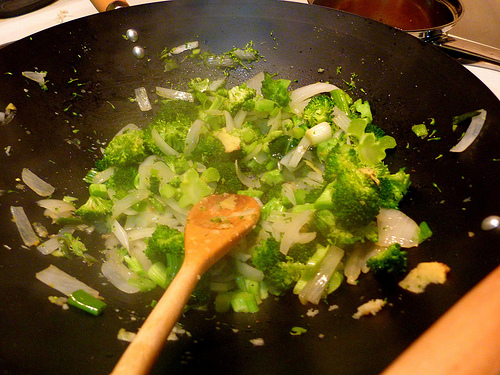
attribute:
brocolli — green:
[218, 116, 368, 236]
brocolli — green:
[228, 110, 418, 230]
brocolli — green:
[228, 98, 466, 268]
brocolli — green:
[195, 101, 391, 243]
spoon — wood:
[86, 171, 305, 364]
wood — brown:
[107, 168, 287, 372]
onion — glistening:
[15, 161, 122, 354]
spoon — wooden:
[105, 201, 253, 371]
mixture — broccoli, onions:
[131, 108, 352, 252]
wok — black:
[2, 2, 479, 372]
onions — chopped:
[99, 190, 184, 245]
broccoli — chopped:
[286, 132, 378, 252]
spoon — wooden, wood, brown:
[104, 193, 264, 373]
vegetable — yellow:
[392, 257, 455, 297]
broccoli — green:
[146, 222, 189, 288]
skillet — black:
[4, 3, 484, 373]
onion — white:
[441, 109, 484, 154]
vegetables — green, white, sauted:
[76, 70, 436, 318]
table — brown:
[353, 242, 498, 372]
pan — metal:
[312, 0, 466, 54]